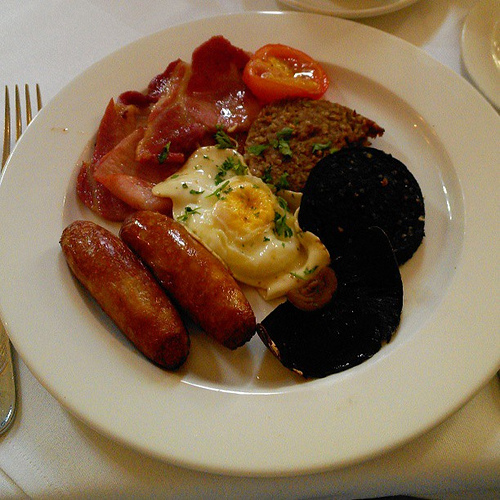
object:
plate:
[0, 9, 500, 478]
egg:
[152, 146, 333, 302]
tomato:
[241, 43, 330, 107]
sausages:
[58, 209, 257, 370]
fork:
[0, 83, 43, 436]